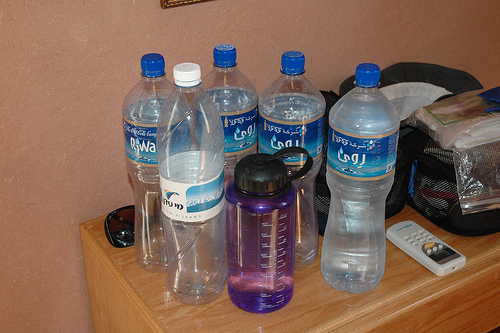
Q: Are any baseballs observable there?
A: No, there are no baseballs.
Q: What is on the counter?
A: The bottles are on the counter.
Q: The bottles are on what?
A: The bottles are on the counter.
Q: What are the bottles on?
A: The bottles are on the counter.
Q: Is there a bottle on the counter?
A: Yes, there are bottles on the counter.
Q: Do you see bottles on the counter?
A: Yes, there are bottles on the counter.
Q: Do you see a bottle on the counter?
A: Yes, there are bottles on the counter.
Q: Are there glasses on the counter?
A: No, there are bottles on the counter.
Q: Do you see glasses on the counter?
A: No, there are bottles on the counter.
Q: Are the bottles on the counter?
A: Yes, the bottles are on the counter.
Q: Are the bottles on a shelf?
A: No, the bottles are on the counter.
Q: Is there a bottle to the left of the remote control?
A: Yes, there are bottles to the left of the remote control.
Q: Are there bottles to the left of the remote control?
A: Yes, there are bottles to the left of the remote control.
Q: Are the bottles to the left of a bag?
A: No, the bottles are to the left of the remote.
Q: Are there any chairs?
A: No, there are no chairs.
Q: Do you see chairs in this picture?
A: No, there are no chairs.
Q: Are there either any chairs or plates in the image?
A: No, there are no chairs or plates.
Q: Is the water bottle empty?
A: Yes, the water bottle is empty.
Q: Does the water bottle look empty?
A: Yes, the water bottle is empty.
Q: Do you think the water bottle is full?
A: No, the water bottle is empty.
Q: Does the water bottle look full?
A: No, the water bottle is empty.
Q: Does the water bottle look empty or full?
A: The water bottle is empty.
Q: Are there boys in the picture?
A: No, there are no boys.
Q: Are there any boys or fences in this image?
A: No, there are no boys or fences.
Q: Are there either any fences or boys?
A: No, there are no boys or fences.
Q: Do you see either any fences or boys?
A: No, there are no boys or fences.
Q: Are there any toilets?
A: No, there are no toilets.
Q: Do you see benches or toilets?
A: No, there are no toilets or benches.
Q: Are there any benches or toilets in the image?
A: No, there are no toilets or benches.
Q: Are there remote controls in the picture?
A: Yes, there is a remote control.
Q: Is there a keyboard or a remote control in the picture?
A: Yes, there is a remote control.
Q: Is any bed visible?
A: No, there are no beds.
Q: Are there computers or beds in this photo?
A: No, there are no beds or computers.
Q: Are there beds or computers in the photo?
A: No, there are no beds or computers.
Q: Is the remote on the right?
A: Yes, the remote is on the right of the image.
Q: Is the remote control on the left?
A: No, the remote control is on the right of the image.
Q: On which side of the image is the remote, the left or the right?
A: The remote is on the right of the image.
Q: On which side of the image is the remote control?
A: The remote control is on the right of the image.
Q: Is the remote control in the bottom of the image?
A: Yes, the remote control is in the bottom of the image.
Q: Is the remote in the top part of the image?
A: No, the remote is in the bottom of the image.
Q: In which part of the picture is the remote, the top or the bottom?
A: The remote is in the bottom of the image.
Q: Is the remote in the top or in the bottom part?
A: The remote is in the bottom of the image.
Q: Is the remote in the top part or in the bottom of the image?
A: The remote is in the bottom of the image.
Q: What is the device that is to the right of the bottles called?
A: The device is a remote control.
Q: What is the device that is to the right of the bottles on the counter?
A: The device is a remote control.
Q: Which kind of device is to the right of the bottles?
A: The device is a remote control.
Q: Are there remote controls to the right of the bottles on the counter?
A: Yes, there is a remote control to the right of the bottles.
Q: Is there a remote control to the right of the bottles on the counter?
A: Yes, there is a remote control to the right of the bottles.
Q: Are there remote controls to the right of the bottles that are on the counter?
A: Yes, there is a remote control to the right of the bottles.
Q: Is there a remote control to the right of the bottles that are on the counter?
A: Yes, there is a remote control to the right of the bottles.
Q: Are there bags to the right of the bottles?
A: No, there is a remote control to the right of the bottles.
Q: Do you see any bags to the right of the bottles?
A: No, there is a remote control to the right of the bottles.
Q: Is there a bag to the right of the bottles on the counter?
A: No, there is a remote control to the right of the bottles.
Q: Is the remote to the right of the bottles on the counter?
A: Yes, the remote is to the right of the bottles.